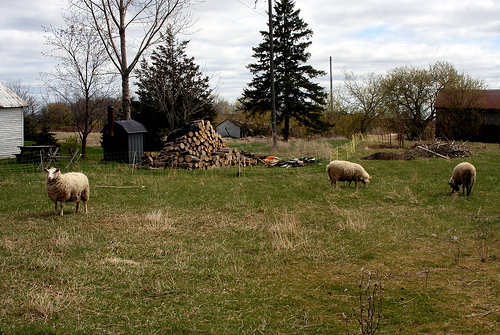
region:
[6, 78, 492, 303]
Sheep grazing in a field.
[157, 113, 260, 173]
A stack of cut wood.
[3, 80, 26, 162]
Part of a white building on the left.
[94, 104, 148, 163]
A small black building.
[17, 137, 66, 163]
A wood picnic table.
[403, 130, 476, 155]
A pile of dried limbs.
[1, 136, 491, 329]
The grass is green and brown.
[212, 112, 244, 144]
A white building in middle of picture.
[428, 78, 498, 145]
An older building on far right.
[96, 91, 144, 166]
A small smokestack on little black building.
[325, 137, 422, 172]
Big giraffes standing in the ground.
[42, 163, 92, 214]
a sheep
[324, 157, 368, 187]
the shepe is white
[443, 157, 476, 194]
the sheep is eating grass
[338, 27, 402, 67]
the clouds are white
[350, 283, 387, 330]
a branch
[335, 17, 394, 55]
the clouds are white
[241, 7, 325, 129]
a tall tree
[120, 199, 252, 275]
the grass is dead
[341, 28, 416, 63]
the sky is cloudy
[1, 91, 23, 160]
a white house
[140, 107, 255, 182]
a pile of logs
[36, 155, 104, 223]
the sheep is watching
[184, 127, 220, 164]
stack of fire wood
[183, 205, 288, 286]
brown and green grass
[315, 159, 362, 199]
brown and white sheep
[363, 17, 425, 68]
blue and white sky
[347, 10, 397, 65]
white clouds in sky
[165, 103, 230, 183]
tall pile of wood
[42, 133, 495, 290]
three sheep in field